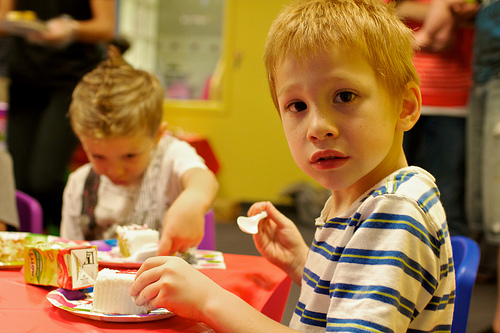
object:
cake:
[93, 267, 155, 317]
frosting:
[95, 268, 138, 284]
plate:
[44, 288, 180, 322]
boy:
[138, 3, 455, 329]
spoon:
[233, 210, 269, 233]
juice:
[21, 240, 100, 289]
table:
[5, 238, 289, 326]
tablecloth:
[200, 246, 294, 316]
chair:
[448, 228, 484, 332]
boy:
[57, 63, 223, 257]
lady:
[4, 3, 97, 217]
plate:
[8, 10, 48, 35]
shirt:
[288, 166, 457, 329]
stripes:
[340, 239, 446, 286]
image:
[4, 7, 490, 322]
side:
[27, 275, 88, 295]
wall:
[221, 13, 280, 197]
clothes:
[10, 7, 79, 161]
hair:
[264, 0, 423, 97]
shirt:
[60, 135, 206, 240]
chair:
[197, 212, 224, 251]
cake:
[109, 221, 159, 261]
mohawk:
[86, 45, 131, 134]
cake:
[7, 8, 41, 20]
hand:
[247, 202, 305, 272]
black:
[9, 72, 28, 89]